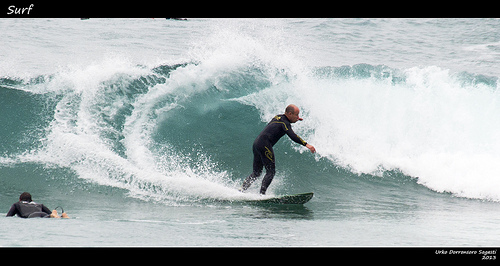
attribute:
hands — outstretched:
[293, 112, 325, 154]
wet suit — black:
[241, 113, 305, 194]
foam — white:
[8, 29, 498, 91]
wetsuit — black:
[239, 114, 300, 182]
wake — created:
[75, 117, 170, 193]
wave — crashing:
[312, 54, 403, 152]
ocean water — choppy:
[2, 17, 499, 244]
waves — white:
[3, 40, 498, 258]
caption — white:
[432, 243, 498, 262]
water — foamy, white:
[13, 25, 494, 205]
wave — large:
[7, 45, 499, 207]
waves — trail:
[3, 17, 498, 229]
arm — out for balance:
[284, 128, 323, 155]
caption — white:
[6, 2, 39, 17]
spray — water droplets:
[72, 34, 197, 113]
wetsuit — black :
[247, 112, 304, 191]